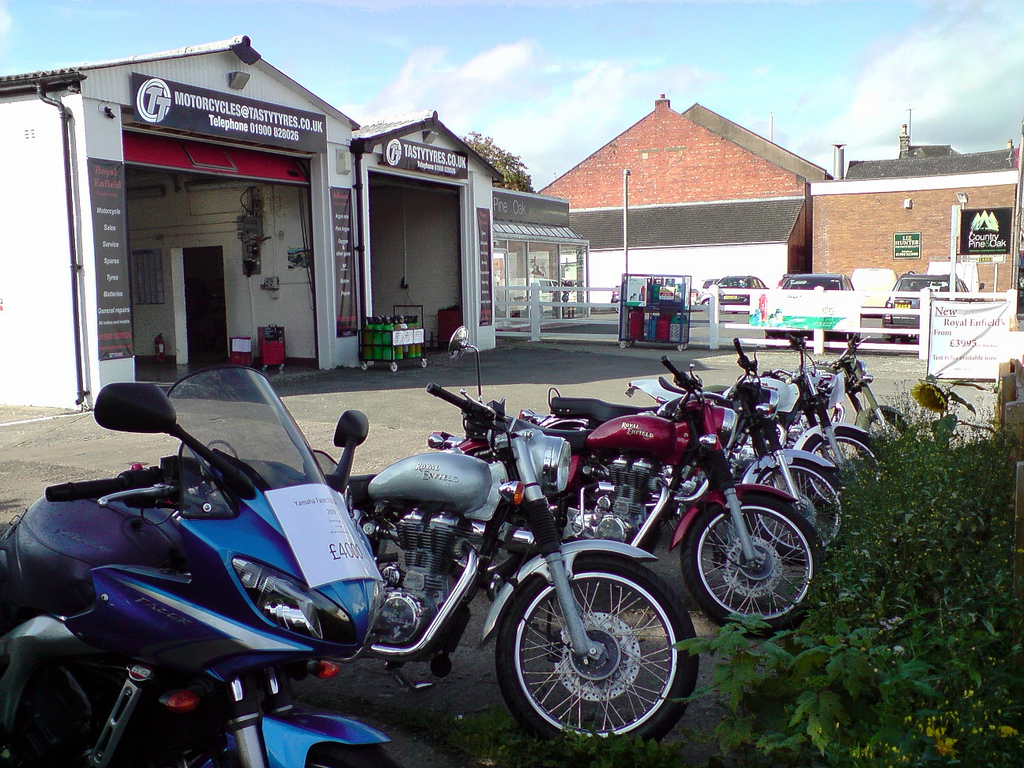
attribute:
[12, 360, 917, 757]
motorcycles — standing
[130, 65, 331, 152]
signboard — black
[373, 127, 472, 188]
signboard — large, black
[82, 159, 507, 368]
signs — black, hanging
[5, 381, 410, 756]
blue motorcycle — parked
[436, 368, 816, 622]
red motorcycle — parked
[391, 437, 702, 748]
bike — parked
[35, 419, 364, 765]
blue bike — parked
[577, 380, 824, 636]
red bike — parked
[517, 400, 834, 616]
red bike — parked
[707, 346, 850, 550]
bike — parked, white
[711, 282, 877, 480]
bike — white, parked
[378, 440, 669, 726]
bike — silver, parked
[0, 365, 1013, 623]
road — paved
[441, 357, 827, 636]
bike — parked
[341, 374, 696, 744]
motorcycle — parked, silver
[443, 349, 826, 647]
motorcycle — silver, parked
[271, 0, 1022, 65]
sky — blue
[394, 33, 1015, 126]
clouds — white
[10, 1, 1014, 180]
sky — blue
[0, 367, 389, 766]
motorcycle — blue, parked, white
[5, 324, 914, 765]
motorcycle — parked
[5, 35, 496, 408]
warehouses — white, black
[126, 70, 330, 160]
banner — blue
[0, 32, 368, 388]
warehouse — white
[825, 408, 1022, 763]
bushes — green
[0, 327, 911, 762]
motorcycles — parked, cloudy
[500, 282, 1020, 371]
fence — white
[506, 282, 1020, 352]
fence — white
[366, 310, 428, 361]
canisters — green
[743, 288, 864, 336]
sign — white, red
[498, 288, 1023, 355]
fence — white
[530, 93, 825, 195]
building top — brick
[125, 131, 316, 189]
garage door — red, raised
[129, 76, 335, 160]
sign — white and black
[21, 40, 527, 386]
house — white